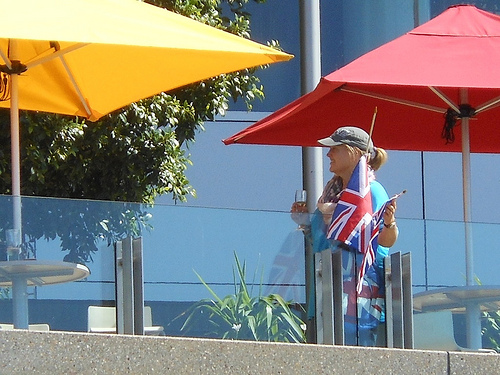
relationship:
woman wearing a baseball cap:
[291, 124, 400, 344] [319, 126, 374, 159]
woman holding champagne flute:
[291, 124, 400, 344] [295, 190, 308, 231]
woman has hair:
[291, 124, 400, 344] [342, 143, 388, 173]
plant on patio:
[166, 249, 306, 342] [0, 193, 498, 373]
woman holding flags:
[291, 124, 400, 344] [326, 152, 399, 294]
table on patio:
[414, 285, 499, 351] [0, 193, 498, 373]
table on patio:
[0, 260, 91, 330] [0, 193, 498, 373]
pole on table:
[460, 88, 472, 289] [414, 285, 499, 351]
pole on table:
[8, 41, 25, 259] [0, 260, 91, 330]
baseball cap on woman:
[319, 126, 374, 159] [291, 124, 400, 344]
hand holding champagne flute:
[289, 203, 312, 226] [295, 190, 308, 231]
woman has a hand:
[291, 124, 400, 344] [289, 203, 312, 226]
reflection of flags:
[262, 231, 306, 302] [326, 152, 399, 294]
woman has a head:
[291, 124, 400, 344] [326, 126, 373, 175]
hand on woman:
[289, 203, 312, 226] [291, 124, 400, 344]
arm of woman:
[379, 221, 399, 248] [291, 124, 400, 344]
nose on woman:
[326, 150, 332, 157] [291, 124, 400, 344]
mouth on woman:
[327, 156, 335, 164] [291, 124, 400, 344]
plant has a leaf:
[166, 249, 306, 342] [192, 267, 231, 312]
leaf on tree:
[189, 188, 196, 197] [0, 2, 283, 283]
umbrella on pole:
[223, 2, 499, 155] [460, 88, 472, 289]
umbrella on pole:
[0, 2, 295, 122] [8, 41, 25, 259]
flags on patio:
[326, 152, 399, 294] [0, 193, 498, 373]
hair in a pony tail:
[342, 143, 388, 173] [372, 146, 386, 171]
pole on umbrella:
[460, 88, 472, 289] [223, 2, 499, 155]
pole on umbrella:
[8, 41, 25, 259] [0, 2, 295, 122]